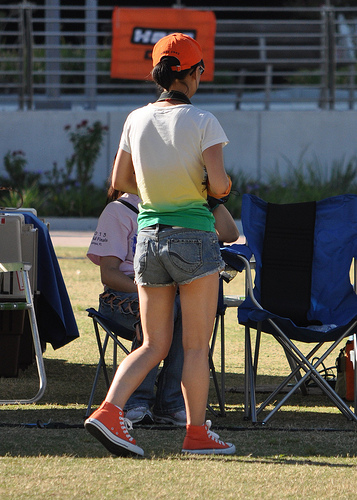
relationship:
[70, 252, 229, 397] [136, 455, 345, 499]
black lawn chair on grass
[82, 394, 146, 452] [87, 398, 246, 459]
orange shoe on foot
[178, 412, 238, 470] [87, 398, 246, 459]
right orange sneaker on foot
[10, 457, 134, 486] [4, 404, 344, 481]
grass on ground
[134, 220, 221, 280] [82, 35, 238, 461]
blue denim shorts on girl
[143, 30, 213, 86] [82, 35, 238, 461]
baseball cap on girl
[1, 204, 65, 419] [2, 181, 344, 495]
chair folded up folded ground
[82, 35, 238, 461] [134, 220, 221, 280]
girl wearing blue denim shorts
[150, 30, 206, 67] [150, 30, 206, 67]
baseball cap wearing baseball cap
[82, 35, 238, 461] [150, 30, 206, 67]
girl wearing baseball cap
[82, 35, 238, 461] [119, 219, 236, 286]
girl wearing blue jean shorts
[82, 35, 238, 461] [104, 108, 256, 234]
girl wearing green t shirt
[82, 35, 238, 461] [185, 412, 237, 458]
girl in right orange sneaker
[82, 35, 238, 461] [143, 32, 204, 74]
girl in hat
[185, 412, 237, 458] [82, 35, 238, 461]
right orange sneaker on girl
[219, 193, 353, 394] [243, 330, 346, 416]
blue chair with base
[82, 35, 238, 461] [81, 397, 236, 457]
girl with shoes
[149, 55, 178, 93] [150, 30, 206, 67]
black pony tail sticking baseball cap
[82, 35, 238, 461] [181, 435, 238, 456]
girl has foot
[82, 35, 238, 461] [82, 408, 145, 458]
girl has foot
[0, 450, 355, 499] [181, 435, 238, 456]
ground behind foot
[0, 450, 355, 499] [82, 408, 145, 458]
ground behind foot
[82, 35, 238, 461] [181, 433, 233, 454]
girl has foot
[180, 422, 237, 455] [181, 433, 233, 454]
sneaker on foot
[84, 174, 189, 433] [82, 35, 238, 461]
woman behind girl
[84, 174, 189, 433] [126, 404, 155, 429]
woman has foot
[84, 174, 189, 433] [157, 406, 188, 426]
woman has foot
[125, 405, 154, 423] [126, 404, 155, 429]
sneaker on foot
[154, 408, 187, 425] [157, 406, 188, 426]
sneaker on foot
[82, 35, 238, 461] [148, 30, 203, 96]
girl has head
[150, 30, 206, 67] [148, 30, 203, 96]
baseball cap on head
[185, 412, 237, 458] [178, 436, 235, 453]
right orange sneaker on foot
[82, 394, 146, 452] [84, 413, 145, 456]
orange shoe on foot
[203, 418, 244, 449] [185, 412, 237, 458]
white shoelaces on right orange sneaker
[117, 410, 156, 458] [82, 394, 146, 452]
white shoelaces on orange shoe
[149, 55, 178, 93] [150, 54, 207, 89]
black pony tail in hair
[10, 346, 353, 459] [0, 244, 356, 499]
shaded area in grass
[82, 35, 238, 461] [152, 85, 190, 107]
girl has neck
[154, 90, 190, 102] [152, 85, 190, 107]
strap around neck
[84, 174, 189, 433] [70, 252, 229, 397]
woman sitting in black lawn chair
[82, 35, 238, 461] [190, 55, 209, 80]
girl wearing pair of glasses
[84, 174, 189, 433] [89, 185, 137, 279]
woman wearing pink tee shirt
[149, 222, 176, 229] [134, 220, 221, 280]
belt on blue denim shorts